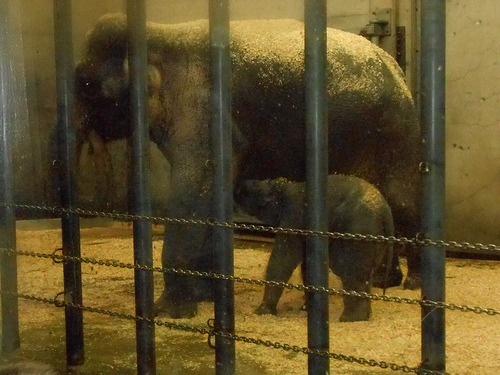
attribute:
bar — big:
[50, 0, 83, 370]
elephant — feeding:
[80, 18, 436, 208]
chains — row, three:
[7, 200, 499, 373]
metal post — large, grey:
[0, 7, 30, 365]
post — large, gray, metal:
[413, 1, 449, 372]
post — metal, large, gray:
[283, 7, 360, 369]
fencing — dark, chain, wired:
[3, 196, 498, 371]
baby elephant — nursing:
[231, 176, 391, 324]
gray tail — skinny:
[379, 237, 395, 297]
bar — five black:
[416, 2, 455, 369]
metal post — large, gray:
[145, 36, 487, 373]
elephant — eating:
[39, 8, 440, 318]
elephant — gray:
[54, 10, 417, 321]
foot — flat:
[255, 301, 281, 318]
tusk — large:
[80, 124, 115, 180]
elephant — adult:
[43, 9, 243, 301]